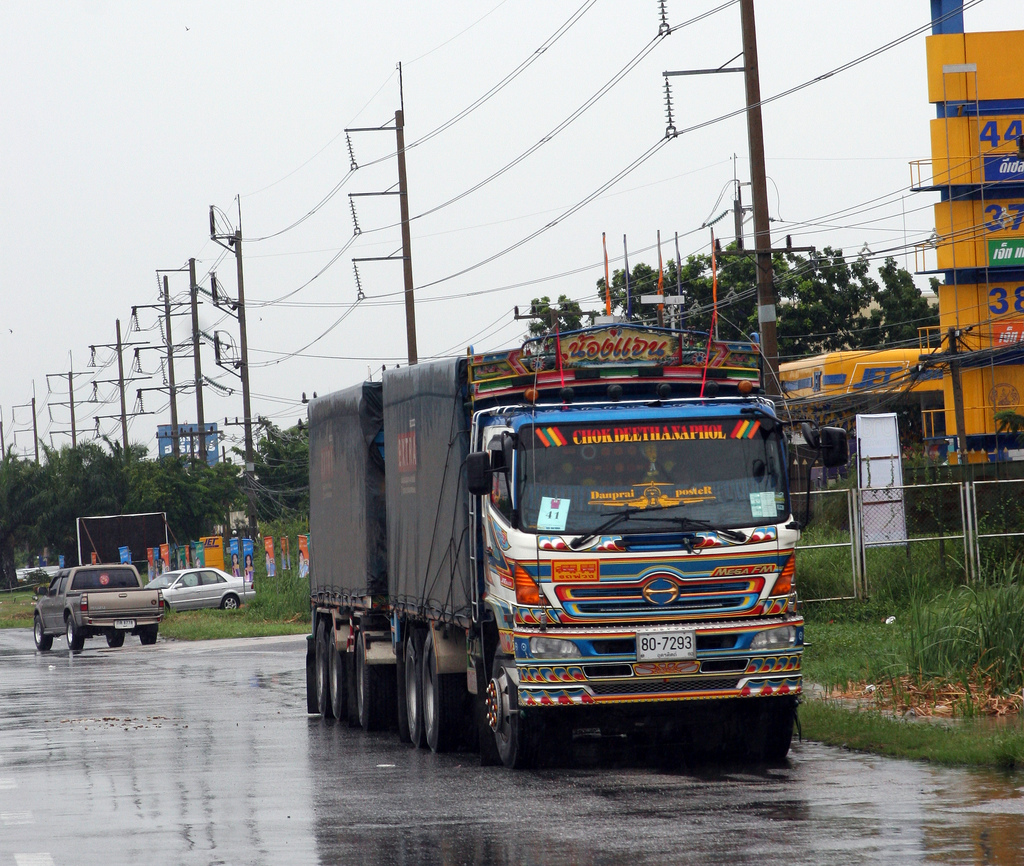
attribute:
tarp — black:
[376, 348, 480, 636]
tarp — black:
[296, 372, 379, 623]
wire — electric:
[257, 132, 392, 245]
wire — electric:
[242, 212, 402, 318]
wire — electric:
[246, 281, 400, 368]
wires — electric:
[257, 127, 405, 383]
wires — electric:
[652, 0, 750, 266]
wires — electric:
[184, 212, 334, 387]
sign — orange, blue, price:
[927, 28, 1020, 461]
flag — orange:
[257, 529, 281, 558]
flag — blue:
[186, 529, 213, 566]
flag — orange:
[147, 533, 169, 572]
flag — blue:
[108, 540, 137, 566]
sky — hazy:
[9, 6, 1021, 497]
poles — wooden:
[65, 2, 802, 486]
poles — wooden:
[6, 2, 799, 504]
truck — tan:
[20, 568, 183, 657]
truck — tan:
[13, 546, 176, 665]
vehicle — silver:
[132, 561, 280, 628]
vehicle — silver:
[136, 550, 255, 620]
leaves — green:
[601, 267, 936, 389]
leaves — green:
[531, 255, 936, 370]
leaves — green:
[125, 397, 270, 560]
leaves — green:
[132, 430, 243, 549]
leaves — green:
[110, 438, 225, 553]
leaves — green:
[50, 437, 226, 546]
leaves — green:
[210, 419, 316, 519]